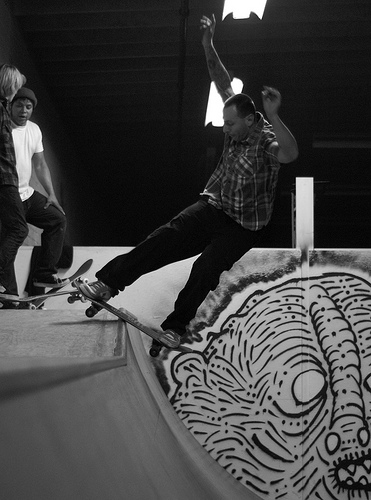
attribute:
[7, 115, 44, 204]
shirt — white 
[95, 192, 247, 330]
jeans — dark 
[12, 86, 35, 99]
beanie hat — beanie 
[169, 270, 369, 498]
drawing — graffiti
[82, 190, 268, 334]
pants — black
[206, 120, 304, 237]
shirt — striped, short sleeve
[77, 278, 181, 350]
shoes — gray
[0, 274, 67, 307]
shoes — gray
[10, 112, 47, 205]
shirt — white